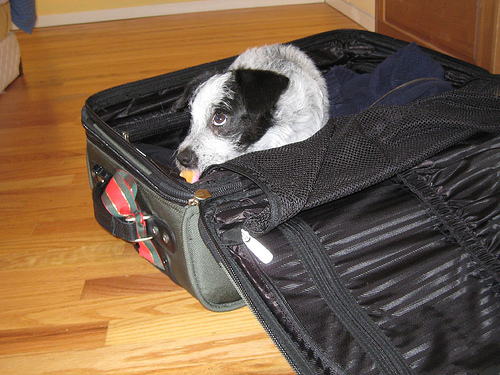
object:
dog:
[178, 44, 331, 182]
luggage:
[82, 26, 499, 374]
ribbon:
[102, 170, 166, 270]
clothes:
[327, 43, 446, 116]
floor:
[2, 2, 368, 375]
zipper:
[121, 130, 129, 140]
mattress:
[0, 1, 21, 93]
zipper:
[187, 189, 211, 205]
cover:
[206, 133, 499, 374]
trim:
[36, 1, 376, 33]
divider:
[198, 91, 500, 227]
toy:
[180, 169, 199, 184]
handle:
[89, 166, 175, 254]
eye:
[213, 114, 226, 125]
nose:
[177, 149, 191, 166]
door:
[374, 0, 499, 78]